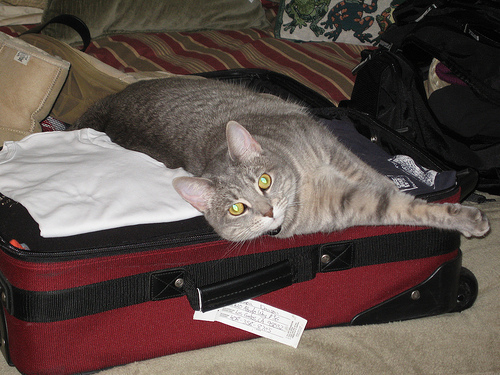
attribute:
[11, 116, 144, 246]
shirt — white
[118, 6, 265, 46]
pillow — dark grey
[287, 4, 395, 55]
pillow — green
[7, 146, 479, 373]
suitcase — red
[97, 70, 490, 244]
fur — gray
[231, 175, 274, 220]
eyes — green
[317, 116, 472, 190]
clothing — white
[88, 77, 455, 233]
cat — grey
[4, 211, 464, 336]
bag — red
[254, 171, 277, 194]
pupil — green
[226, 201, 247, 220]
pupil — green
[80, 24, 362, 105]
sheet — red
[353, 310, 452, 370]
beige carpet — dark beige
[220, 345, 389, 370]
beige blanket — green, burgundy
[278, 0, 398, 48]
pillow with frogs — pink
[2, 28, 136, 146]
pair of boots — beige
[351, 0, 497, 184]
open back pack — big, black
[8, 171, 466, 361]
black suit case — urgundy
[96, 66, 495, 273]
beautiful cat — grey, striped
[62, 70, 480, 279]
adult cat — beautiful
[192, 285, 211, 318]
string on name tag — white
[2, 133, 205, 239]
folded tee shirt — white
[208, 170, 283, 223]
green eyes on cat — mesmerizing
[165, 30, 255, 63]
green striped fabric — burgundy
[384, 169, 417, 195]
white design — navy blue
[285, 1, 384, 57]
frog print pillow — frog print